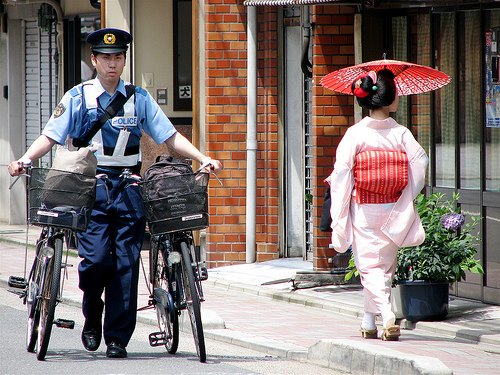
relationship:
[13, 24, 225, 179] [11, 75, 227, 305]
policeman in uniform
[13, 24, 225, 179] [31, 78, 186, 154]
policeman in blue uniform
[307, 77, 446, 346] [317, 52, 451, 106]
woman has red umbrella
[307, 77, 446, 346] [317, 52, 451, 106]
lady carrying parasol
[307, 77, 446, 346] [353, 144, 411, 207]
lady has back pack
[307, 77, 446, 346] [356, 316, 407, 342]
lady wearing clogs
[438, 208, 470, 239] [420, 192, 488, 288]
flower on bush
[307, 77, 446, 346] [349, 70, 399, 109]
lady has dark hair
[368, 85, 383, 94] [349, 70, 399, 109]
ornaments in hair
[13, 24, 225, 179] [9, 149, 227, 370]
policeman has two bikes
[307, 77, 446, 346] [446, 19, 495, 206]
lady looking in window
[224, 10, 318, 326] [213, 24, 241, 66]
building made of brick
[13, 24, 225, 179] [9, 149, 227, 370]
policeman walks two bicycles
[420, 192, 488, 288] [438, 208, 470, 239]
potted plant with purple flower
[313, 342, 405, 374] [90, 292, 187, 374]
curb at road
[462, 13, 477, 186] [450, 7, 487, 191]
windows with brown frames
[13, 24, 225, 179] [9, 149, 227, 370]
police man walking two bicycles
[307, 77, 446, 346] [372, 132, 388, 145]
woman wearing pink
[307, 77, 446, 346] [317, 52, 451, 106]
asian woman holding parasol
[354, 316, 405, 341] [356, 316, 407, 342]
pair of wooden sandals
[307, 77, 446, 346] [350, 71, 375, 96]
woman with intricate bun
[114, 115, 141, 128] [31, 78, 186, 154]
tag on a outfit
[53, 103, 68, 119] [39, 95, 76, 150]
police badge on sleeve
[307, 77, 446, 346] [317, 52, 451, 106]
woman holding red umbrella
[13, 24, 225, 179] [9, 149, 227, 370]
man pushing two bikes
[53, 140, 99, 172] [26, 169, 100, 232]
bag in basket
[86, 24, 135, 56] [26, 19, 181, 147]
hat on man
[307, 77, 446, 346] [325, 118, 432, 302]
woman in a kimono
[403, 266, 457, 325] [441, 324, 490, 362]
pot on ground